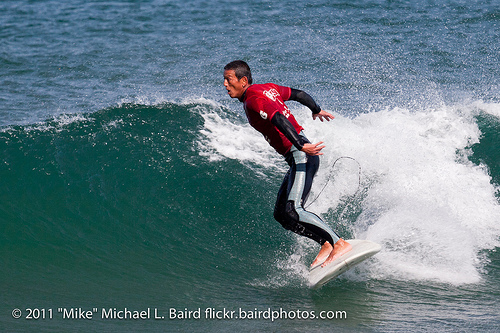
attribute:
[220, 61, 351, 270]
man — surfing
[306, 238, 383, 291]
surfboard — white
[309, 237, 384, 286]
surf board — white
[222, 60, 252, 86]
hair — black, brown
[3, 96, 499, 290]
wave — white, green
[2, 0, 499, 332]
water — light blue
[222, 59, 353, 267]
surfer — male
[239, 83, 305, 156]
shirt — red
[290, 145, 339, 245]
stripe — silver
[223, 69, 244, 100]
face — red